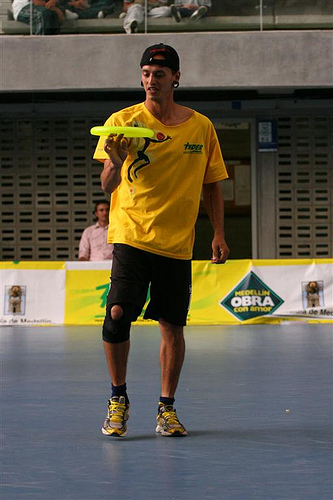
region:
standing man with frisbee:
[91, 42, 229, 436]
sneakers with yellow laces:
[102, 396, 188, 436]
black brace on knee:
[102, 303, 132, 342]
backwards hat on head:
[140, 42, 179, 100]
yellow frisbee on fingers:
[90, 125, 153, 166]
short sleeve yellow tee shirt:
[93, 104, 228, 260]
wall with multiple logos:
[0, 257, 331, 324]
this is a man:
[71, 28, 263, 469]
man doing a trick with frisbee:
[73, 49, 240, 470]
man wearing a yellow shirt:
[85, 99, 258, 260]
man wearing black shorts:
[87, 228, 213, 330]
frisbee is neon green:
[83, 114, 182, 187]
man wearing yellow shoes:
[91, 380, 194, 461]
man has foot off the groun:
[78, 339, 145, 454]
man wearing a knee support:
[88, 278, 142, 366]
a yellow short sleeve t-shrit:
[92, 100, 229, 261]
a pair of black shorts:
[100, 241, 192, 345]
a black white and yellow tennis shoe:
[102, 398, 131, 437]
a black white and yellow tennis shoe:
[155, 405, 188, 435]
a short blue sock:
[107, 381, 126, 398]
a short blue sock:
[157, 393, 175, 407]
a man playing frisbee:
[91, 42, 230, 438]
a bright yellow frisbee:
[89, 124, 155, 138]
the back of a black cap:
[140, 42, 179, 71]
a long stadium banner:
[1, 259, 332, 323]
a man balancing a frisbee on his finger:
[89, 41, 230, 440]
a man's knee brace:
[103, 298, 133, 343]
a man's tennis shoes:
[101, 395, 191, 438]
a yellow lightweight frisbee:
[89, 125, 156, 138]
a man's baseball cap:
[135, 43, 182, 68]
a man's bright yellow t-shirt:
[90, 98, 232, 262]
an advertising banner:
[0, 259, 331, 327]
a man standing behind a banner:
[77, 199, 117, 258]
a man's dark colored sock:
[109, 382, 129, 408]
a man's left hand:
[211, 237, 232, 266]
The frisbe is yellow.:
[86, 119, 157, 142]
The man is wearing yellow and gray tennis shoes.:
[102, 395, 188, 442]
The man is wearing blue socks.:
[103, 379, 175, 409]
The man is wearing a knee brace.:
[95, 299, 137, 347]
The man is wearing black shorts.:
[104, 241, 195, 326]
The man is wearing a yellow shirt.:
[85, 105, 229, 261]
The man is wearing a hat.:
[128, 42, 188, 103]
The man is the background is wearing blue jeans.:
[16, 5, 58, 33]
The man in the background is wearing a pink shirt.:
[75, 221, 113, 262]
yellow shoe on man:
[95, 388, 137, 445]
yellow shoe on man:
[149, 402, 204, 455]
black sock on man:
[102, 382, 134, 399]